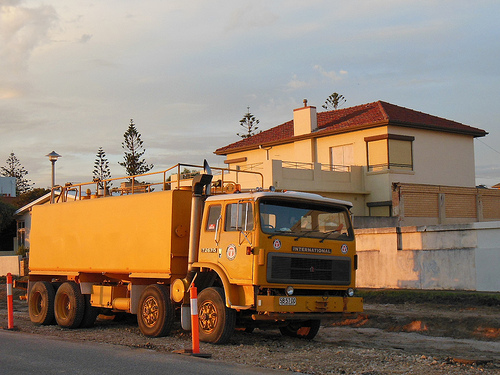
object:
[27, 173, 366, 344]
truck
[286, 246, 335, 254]
writing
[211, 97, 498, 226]
house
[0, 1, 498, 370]
photo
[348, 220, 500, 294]
fence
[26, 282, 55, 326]
wheel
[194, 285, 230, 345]
wheel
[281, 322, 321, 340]
wheel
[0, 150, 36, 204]
tree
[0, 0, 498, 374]
background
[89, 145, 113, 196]
tree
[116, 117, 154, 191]
tree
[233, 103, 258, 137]
tree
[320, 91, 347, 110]
tree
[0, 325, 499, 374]
road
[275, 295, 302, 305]
license plate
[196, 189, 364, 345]
cab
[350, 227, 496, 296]
wall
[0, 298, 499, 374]
gravel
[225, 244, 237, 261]
logo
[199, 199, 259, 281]
door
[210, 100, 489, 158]
roof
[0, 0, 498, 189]
sky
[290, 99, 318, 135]
chimney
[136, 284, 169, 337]
tires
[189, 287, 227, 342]
rims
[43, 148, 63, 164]
light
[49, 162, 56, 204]
pole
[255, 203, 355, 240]
window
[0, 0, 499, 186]
cloud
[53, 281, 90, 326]
back tires